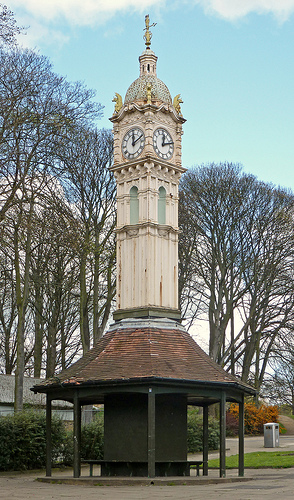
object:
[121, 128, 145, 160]
clock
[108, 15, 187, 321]
tower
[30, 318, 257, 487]
building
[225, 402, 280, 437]
bush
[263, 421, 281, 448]
trash can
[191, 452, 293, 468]
grass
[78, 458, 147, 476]
bench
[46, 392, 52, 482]
posts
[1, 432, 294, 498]
sidewalk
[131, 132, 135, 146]
short hand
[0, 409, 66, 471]
bush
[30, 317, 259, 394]
roof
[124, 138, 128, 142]
roman numerals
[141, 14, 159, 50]
weather vain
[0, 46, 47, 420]
trees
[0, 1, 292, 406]
clouds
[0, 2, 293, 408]
sky